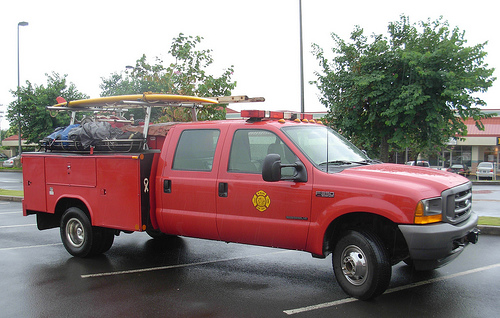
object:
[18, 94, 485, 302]
truck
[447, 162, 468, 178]
vehicles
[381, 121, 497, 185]
background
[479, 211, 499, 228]
strip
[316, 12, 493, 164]
tree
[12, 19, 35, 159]
pole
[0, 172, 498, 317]
parking lot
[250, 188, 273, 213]
insignia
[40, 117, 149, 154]
equipment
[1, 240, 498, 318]
pavement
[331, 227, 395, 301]
tire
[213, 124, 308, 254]
door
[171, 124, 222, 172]
window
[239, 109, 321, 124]
lights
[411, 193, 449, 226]
headlight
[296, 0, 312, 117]
post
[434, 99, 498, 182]
building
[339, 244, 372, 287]
hubcap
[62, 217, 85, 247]
hubcap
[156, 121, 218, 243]
door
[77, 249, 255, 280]
line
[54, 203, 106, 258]
tire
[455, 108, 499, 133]
roof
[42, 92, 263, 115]
grill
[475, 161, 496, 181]
car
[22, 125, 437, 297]
side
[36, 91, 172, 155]
cargo